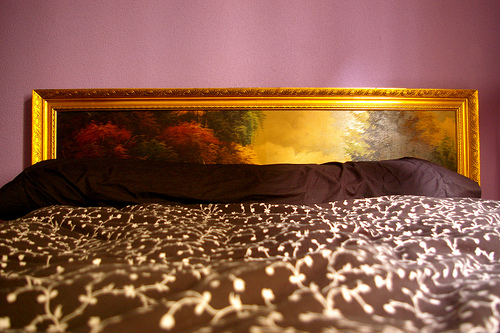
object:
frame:
[19, 86, 98, 146]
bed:
[0, 155, 498, 332]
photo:
[56, 110, 457, 173]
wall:
[0, 0, 500, 88]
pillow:
[63, 160, 411, 198]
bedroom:
[0, 0, 498, 330]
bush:
[68, 120, 150, 157]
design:
[168, 249, 211, 281]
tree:
[344, 111, 457, 170]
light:
[326, 75, 402, 149]